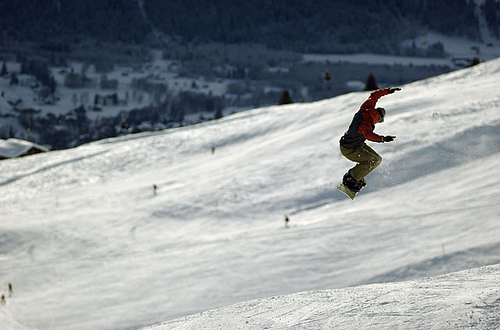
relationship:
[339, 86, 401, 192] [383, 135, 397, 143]
person has glove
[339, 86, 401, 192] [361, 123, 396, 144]
man has arm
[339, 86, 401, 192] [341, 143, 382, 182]
man has pants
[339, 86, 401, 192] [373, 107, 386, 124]
person has head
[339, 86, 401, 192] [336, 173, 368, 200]
person on snowboard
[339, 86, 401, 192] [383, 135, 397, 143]
person wearing glove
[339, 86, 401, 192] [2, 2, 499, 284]
person in air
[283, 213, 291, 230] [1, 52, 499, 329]
person on snow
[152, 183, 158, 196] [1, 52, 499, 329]
person on snow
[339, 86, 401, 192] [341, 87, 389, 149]
person wearing jacket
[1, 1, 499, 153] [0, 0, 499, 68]
mountain has trees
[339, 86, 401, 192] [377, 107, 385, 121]
person has hat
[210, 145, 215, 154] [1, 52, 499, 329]
person on snow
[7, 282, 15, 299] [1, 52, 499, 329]
person on snow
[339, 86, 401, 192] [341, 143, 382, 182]
person has pants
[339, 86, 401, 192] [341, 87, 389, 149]
person has jacket